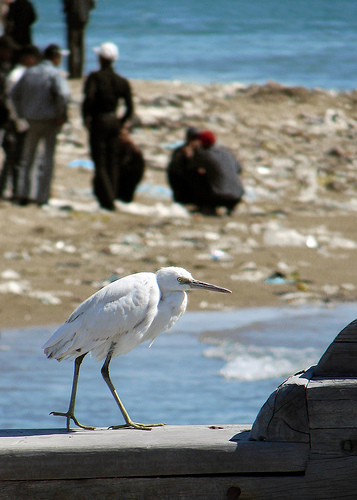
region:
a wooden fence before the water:
[4, 315, 352, 498]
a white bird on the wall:
[36, 267, 238, 433]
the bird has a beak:
[190, 275, 236, 298]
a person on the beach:
[74, 42, 132, 212]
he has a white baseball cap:
[88, 41, 121, 59]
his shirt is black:
[73, 65, 133, 118]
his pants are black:
[82, 108, 131, 210]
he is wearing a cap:
[41, 42, 72, 57]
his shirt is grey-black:
[10, 62, 72, 125]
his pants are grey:
[11, 114, 62, 206]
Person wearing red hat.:
[203, 126, 219, 156]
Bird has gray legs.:
[65, 374, 138, 419]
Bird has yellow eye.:
[169, 269, 188, 295]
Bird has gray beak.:
[186, 267, 254, 314]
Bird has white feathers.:
[68, 262, 196, 357]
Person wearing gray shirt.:
[203, 151, 266, 198]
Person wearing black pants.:
[199, 195, 236, 228]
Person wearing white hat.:
[97, 46, 127, 72]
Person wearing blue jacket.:
[25, 65, 69, 108]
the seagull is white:
[82, 274, 237, 377]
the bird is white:
[44, 265, 187, 395]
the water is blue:
[6, 311, 308, 443]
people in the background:
[31, 25, 249, 212]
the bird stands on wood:
[31, 386, 317, 497]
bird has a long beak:
[191, 280, 229, 304]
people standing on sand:
[32, 141, 312, 331]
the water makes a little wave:
[202, 315, 328, 401]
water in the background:
[68, 4, 351, 74]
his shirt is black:
[196, 150, 237, 195]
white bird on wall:
[40, 265, 205, 439]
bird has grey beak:
[184, 278, 217, 300]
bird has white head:
[160, 258, 193, 299]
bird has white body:
[54, 280, 165, 351]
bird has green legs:
[54, 358, 155, 439]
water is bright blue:
[133, 320, 261, 395]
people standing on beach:
[3, 1, 328, 255]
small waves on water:
[207, 321, 283, 364]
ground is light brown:
[182, 218, 329, 298]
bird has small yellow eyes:
[176, 269, 186, 293]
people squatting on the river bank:
[164, 122, 256, 231]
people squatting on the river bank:
[87, 109, 284, 240]